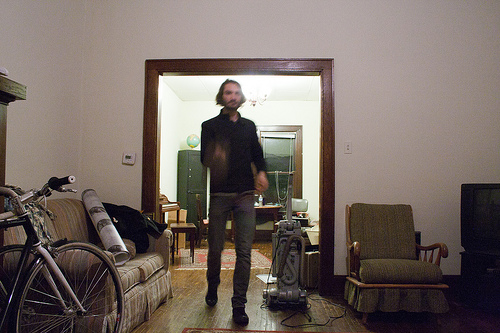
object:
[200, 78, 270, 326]
man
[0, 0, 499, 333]
living room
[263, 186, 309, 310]
vacuum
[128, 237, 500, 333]
floor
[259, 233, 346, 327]
cord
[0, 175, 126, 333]
bike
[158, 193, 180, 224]
piano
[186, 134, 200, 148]
globe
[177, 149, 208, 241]
cabinet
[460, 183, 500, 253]
television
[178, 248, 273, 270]
rug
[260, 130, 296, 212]
window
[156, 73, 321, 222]
wall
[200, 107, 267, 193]
sweater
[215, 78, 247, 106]
hair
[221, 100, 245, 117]
beard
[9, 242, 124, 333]
tire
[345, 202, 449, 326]
chair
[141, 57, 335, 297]
doorway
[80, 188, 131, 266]
poster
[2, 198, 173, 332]
couch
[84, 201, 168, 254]
jacket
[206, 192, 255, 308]
jeans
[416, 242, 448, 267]
armrest